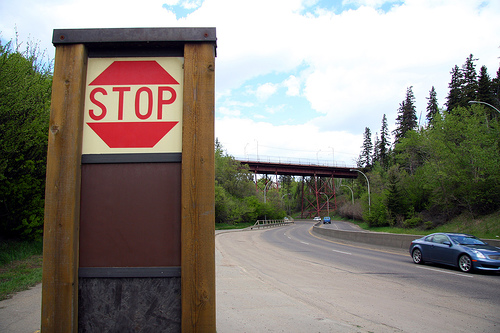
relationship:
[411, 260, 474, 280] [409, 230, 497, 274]
line next to car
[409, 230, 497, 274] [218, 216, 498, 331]
car driving on highway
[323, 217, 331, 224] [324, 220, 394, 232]
car on lane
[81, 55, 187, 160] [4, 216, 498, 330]
sign above ground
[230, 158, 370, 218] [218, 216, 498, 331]
bridge over highway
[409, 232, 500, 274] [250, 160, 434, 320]
car on highway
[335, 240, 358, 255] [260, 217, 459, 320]
line on road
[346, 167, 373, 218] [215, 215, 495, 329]
post next to road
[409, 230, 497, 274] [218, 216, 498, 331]
car on highway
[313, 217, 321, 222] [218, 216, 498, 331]
car on highway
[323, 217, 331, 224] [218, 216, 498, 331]
car on highway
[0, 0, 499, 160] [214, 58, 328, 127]
white cloud in blue sky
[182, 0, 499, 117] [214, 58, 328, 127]
white cloud in blue sky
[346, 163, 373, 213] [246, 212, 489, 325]
light post next road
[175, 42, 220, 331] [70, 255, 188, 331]
post has bottom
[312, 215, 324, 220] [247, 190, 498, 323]
car in highway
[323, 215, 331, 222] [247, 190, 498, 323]
car in highway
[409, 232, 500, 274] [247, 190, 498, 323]
car in highway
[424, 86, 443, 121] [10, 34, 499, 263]
tall trees in park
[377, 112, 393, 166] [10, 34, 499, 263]
tall trees in park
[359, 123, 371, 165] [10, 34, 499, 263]
tall trees in park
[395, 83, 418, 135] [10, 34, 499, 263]
tall trees in park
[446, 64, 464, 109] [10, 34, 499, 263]
tall trees in park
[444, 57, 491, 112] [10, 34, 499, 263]
trees in park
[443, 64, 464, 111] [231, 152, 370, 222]
tall trees in park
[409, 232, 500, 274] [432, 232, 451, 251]
car has window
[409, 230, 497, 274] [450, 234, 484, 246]
car has window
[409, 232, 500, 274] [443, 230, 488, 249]
car has window